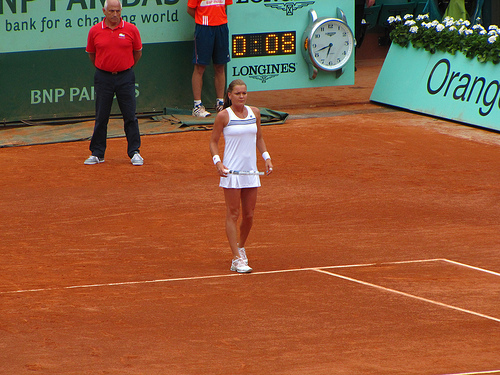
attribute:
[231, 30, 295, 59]
clock — timer, digital, digital timer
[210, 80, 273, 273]
woman — tennis player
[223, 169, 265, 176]
racket — white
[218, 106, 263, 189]
dress — tennis dress, white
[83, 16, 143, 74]
shirt — polo, short sleeve, red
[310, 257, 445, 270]
line — chalk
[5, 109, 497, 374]
tennis court — brown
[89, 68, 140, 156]
pants — black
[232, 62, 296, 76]
writing — logo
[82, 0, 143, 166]
man — standing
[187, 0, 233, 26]
shirt — orange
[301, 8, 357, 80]
analog clock — mounted, watch, silver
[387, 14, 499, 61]
flowers — white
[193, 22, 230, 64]
shorts — blue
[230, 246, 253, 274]
shoes — white